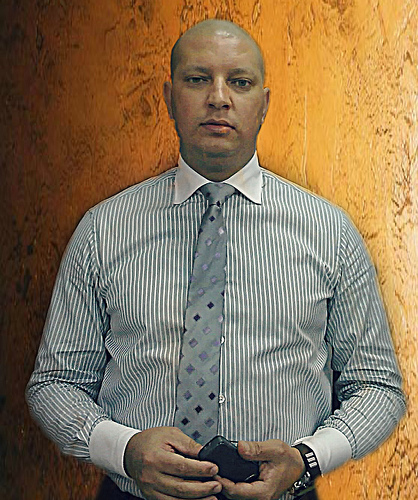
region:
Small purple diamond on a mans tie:
[213, 224, 227, 240]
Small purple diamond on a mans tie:
[202, 234, 217, 248]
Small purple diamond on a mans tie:
[190, 246, 200, 260]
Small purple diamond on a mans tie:
[191, 285, 202, 300]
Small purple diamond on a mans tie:
[204, 273, 224, 289]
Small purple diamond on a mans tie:
[180, 391, 193, 402]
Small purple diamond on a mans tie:
[190, 371, 206, 388]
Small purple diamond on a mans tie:
[205, 364, 222, 377]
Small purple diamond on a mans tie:
[183, 330, 197, 353]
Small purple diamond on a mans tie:
[201, 412, 218, 428]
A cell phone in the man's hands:
[197, 435, 256, 481]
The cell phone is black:
[199, 436, 258, 483]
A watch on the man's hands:
[290, 444, 322, 498]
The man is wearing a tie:
[171, 184, 235, 443]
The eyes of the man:
[185, 73, 248, 87]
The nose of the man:
[205, 82, 231, 110]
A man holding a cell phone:
[27, 19, 408, 498]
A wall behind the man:
[0, 1, 415, 498]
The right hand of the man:
[125, 427, 219, 499]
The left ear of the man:
[261, 85, 269, 121]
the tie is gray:
[172, 174, 238, 452]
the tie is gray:
[177, 189, 240, 488]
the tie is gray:
[178, 187, 244, 438]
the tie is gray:
[156, 173, 227, 454]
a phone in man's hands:
[142, 407, 258, 498]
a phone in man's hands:
[143, 399, 268, 497]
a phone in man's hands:
[154, 401, 254, 492]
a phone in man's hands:
[159, 421, 273, 496]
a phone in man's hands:
[133, 389, 261, 498]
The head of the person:
[157, 9, 271, 163]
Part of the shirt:
[252, 291, 279, 327]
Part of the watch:
[301, 471, 309, 483]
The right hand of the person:
[122, 421, 218, 494]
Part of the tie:
[196, 290, 208, 345]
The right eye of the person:
[180, 71, 203, 82]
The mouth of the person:
[193, 114, 233, 131]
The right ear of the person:
[159, 75, 171, 118]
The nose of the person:
[201, 68, 230, 106]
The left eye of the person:
[226, 77, 253, 88]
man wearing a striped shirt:
[11, 162, 407, 476]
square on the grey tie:
[188, 307, 199, 320]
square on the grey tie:
[204, 297, 212, 305]